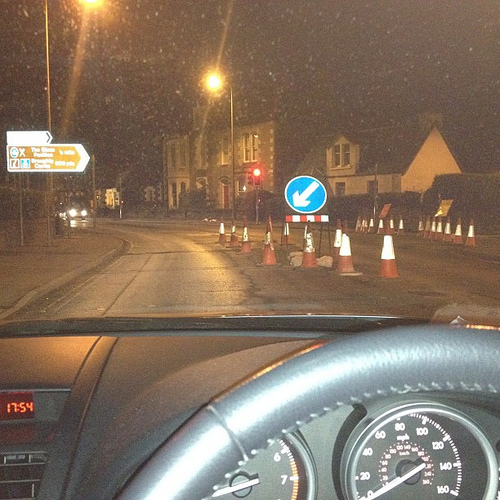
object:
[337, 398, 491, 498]
speedometer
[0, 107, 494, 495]
car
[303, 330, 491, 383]
steering  wheel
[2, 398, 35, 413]
clock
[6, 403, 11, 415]
number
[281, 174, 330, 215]
sign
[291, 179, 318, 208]
arrow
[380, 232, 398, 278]
cone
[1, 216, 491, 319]
street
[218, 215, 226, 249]
cone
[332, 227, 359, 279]
cone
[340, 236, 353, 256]
reflector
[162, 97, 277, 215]
building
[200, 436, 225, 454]
light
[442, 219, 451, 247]
cone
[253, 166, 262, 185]
traffic light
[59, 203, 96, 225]
car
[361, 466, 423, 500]
needle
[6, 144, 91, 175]
sign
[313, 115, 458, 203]
building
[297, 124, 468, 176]
roof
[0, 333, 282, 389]
dash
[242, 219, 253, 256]
cone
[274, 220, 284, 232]
down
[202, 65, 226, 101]
streetlight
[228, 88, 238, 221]
pole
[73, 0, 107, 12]
streetlight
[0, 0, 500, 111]
sky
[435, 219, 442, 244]
cone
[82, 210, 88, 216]
headlight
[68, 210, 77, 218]
headlight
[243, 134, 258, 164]
window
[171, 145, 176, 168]
window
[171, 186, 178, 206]
window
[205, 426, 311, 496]
tachometer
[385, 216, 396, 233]
cone